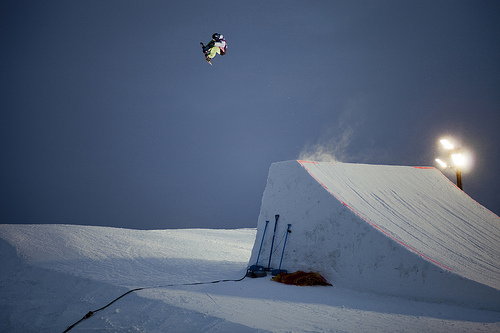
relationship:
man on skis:
[204, 29, 232, 60] [196, 42, 217, 66]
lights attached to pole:
[430, 128, 478, 175] [452, 169, 467, 191]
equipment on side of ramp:
[247, 211, 315, 274] [244, 152, 481, 308]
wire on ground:
[56, 278, 244, 331] [1, 224, 481, 330]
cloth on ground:
[266, 264, 337, 290] [1, 224, 481, 330]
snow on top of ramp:
[332, 169, 480, 237] [244, 152, 481, 308]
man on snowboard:
[204, 29, 232, 60] [193, 40, 217, 70]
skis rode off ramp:
[196, 42, 217, 66] [244, 152, 481, 308]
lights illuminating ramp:
[430, 128, 478, 175] [244, 152, 481, 308]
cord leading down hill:
[119, 285, 182, 301] [249, 164, 500, 313]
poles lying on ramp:
[256, 213, 296, 273] [232, 285, 272, 302]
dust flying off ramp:
[305, 104, 364, 164] [355, 139, 378, 167]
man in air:
[204, 29, 232, 60] [102, 63, 152, 142]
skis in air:
[196, 42, 217, 66] [112, 21, 159, 89]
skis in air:
[196, 42, 217, 66] [114, 20, 170, 87]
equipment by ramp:
[225, 208, 315, 297] [313, 234, 361, 262]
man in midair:
[204, 29, 232, 60] [188, 77, 239, 101]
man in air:
[204, 29, 232, 60] [285, 22, 319, 69]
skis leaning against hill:
[248, 207, 298, 258] [291, 199, 365, 244]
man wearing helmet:
[204, 29, 232, 60] [215, 26, 224, 38]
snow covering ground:
[387, 249, 422, 279] [210, 299, 242, 311]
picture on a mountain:
[225, 106, 449, 282] [125, 210, 175, 266]